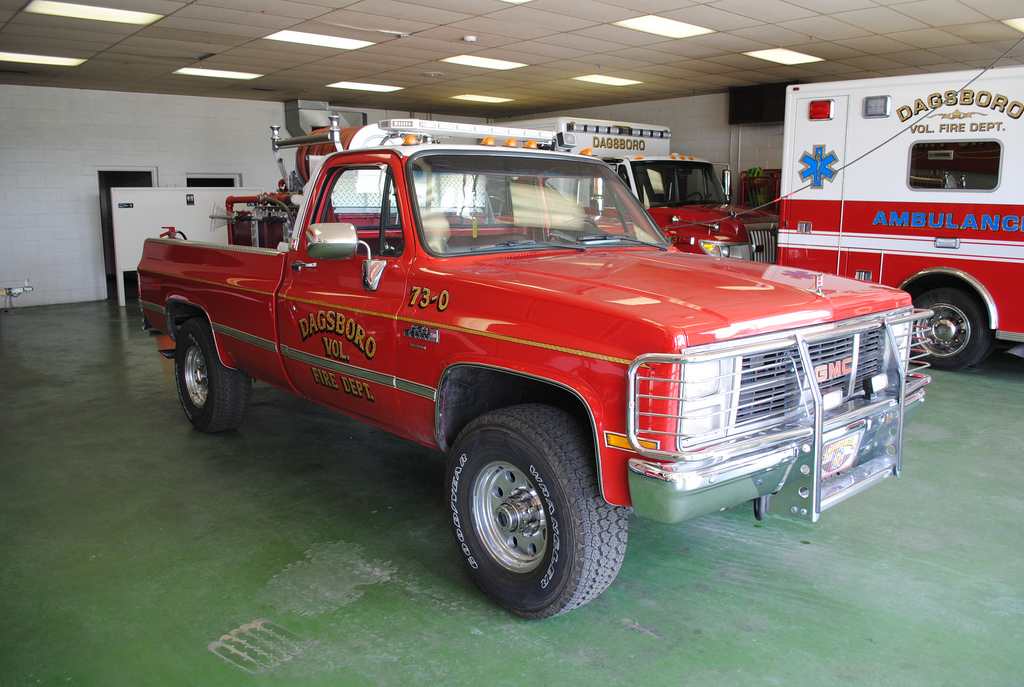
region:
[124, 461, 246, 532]
the floor is green in colour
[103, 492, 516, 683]
Muddy tracks on the floor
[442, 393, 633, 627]
black tire on a truck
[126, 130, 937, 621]
red truck parked in a garage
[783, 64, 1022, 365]
side of an ambulance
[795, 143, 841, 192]
paramedic symbol on an ambulance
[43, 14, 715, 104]
overhead ceiling lights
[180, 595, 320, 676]
tire track on garage floor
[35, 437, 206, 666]
green floor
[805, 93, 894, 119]
red and white ambulance lights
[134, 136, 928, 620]
volunteer fire department pick-up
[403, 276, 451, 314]
numbers 73-0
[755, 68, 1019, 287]
a trailer on an ambulance vehicle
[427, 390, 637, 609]
a large black truck tire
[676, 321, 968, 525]
a bumber guard over a bumper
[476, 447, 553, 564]
the rim of a wheel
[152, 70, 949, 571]
an emergency response truck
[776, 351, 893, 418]
the GMC symbol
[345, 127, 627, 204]
safety light unlit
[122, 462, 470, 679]
a green floor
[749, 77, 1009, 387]
an ambulance truck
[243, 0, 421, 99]
rectangle light fixture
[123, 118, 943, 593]
a red pickup truck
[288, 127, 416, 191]
hosing on back of pickup truck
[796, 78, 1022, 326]
red and white ambulance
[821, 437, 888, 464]
license plate of truck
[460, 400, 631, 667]
front right wheel of truck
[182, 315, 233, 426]
rear white wheel of truck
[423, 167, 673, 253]
windshield of pickup truck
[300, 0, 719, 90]
Ceiling tiles of garage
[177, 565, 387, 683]
tire tracks on floor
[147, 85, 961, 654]
red truck in garage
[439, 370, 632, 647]
tire on a truck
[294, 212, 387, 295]
passenger side mirror on truck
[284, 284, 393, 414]
Dagsboro Vol. Fire Dept.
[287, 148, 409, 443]
door of truck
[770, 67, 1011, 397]
ambulance in a garage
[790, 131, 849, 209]
medical insignia on an ambulance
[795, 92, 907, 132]
lights on side of ambuance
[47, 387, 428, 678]
green floor in garage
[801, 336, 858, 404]
GMC emblem on front of truck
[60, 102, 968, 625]
Firetruck parked in garage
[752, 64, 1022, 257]
Back of ambulance parked in garage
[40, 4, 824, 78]
Ceiling tiles with lights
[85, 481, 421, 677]
Green floor with tire tracks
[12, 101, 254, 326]
Back wall with two doors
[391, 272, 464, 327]
ID number on fire truck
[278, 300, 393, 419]
Fire department name on truck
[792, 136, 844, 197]
Ambulance symbol on ambulance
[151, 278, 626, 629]
Tires on fire truck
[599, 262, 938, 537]
Reinforced front of fire truck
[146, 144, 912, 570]
Red truck in the foreground.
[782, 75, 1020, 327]
Ambulance to the right in the background.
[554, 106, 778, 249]
Ambulance to the left in the background.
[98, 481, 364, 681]
Green cement floor.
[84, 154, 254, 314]
Two door ways.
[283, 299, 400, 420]
Fire department logo in yellow.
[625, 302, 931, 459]
The truck's grill is silver.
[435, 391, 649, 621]
The tire is black.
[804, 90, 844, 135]
Red emergency light.